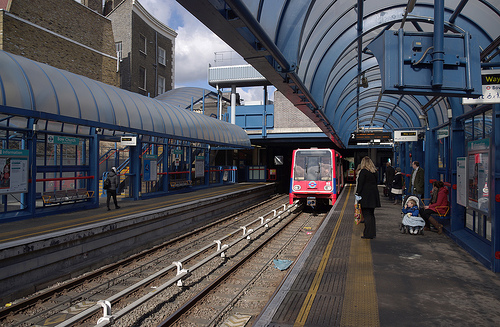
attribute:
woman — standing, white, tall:
[354, 152, 390, 236]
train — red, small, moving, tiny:
[282, 141, 343, 211]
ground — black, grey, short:
[291, 171, 478, 324]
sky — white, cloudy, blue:
[129, 2, 454, 114]